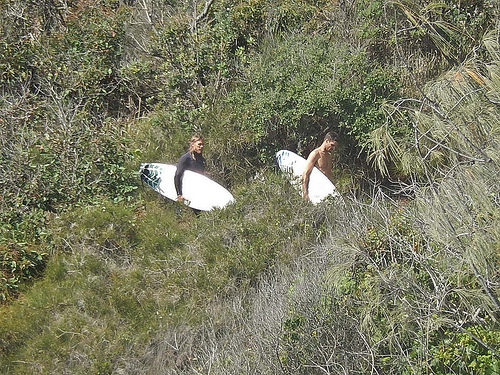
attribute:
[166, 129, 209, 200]
man — walking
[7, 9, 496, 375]
bushes — green, tall, lots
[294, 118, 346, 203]
man — walking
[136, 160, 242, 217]
surfboard — white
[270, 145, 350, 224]
surfboard — white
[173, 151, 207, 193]
wetsuit — black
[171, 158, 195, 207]
arm — long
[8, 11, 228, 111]
trees — green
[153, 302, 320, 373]
grass — dry